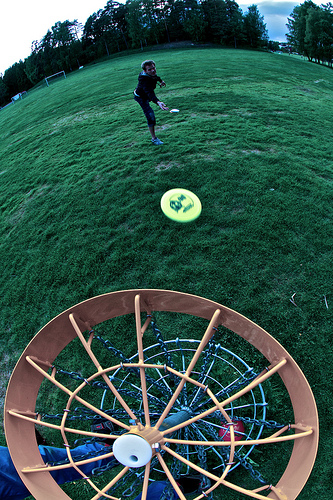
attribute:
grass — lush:
[39, 174, 322, 417]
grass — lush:
[20, 49, 279, 363]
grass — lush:
[62, 66, 272, 343]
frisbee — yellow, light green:
[159, 185, 204, 224]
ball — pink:
[217, 417, 248, 447]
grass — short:
[0, 47, 322, 496]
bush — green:
[180, 1, 269, 52]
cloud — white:
[236, 1, 300, 43]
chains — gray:
[204, 408, 289, 428]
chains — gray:
[190, 422, 268, 498]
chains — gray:
[188, 427, 214, 498]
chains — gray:
[198, 418, 271, 484]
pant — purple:
[0, 441, 113, 498]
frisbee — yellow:
[153, 182, 206, 231]